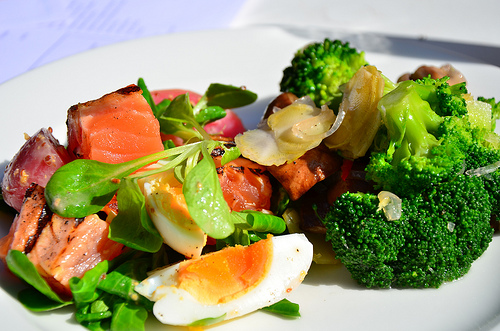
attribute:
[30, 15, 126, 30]
floor — bright white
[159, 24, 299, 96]
plate — white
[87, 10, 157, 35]
surface — white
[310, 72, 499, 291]
cauliflower —  a piece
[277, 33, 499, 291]
brocollis — uncooked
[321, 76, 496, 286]
green vegetable —  green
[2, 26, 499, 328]
plate — full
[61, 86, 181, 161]
carrot —  a piece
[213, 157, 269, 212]
tomatoe —  a piece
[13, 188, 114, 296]
carrot —  a piece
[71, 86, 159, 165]
meat — uncooked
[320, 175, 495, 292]
broccoli — green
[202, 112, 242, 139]
tomato —  a piece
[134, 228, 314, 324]
egg —  half cut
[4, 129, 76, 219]
tomatoe —  a piece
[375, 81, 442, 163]
stalks — bright green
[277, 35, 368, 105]
cauliflower —  a piece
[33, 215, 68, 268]
carrot —  a piece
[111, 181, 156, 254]
leaves — green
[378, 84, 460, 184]
broccoli —  a piece, a cauliflower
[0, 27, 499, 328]
food — colorful, appetizing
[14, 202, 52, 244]
carrot —  a piece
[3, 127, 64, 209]
pieces —  red